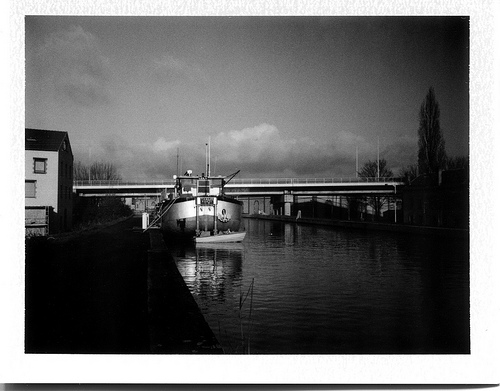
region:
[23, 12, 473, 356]
a black and white photo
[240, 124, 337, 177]
clouds in the sky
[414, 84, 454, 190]
a tree in the distance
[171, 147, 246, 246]
a boat on the water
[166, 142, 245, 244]
a boat parked in the water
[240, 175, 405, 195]
a bridge behind the boat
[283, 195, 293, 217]
column foundation for the bridge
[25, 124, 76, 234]
a house near the water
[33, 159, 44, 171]
a window in the house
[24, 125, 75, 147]
the roof of the house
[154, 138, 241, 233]
a large docked boat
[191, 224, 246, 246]
a small boat in water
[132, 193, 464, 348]
a river of water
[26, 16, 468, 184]
a cloudy hazy sky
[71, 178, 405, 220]
a bridge over water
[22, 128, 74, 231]
a white building in distance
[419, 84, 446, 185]
a tall tree in distance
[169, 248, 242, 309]
reflection of boat in water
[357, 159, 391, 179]
a large tree in distance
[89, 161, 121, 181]
a bare tree in distance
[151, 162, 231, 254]
boat docked on water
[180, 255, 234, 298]
reflection in water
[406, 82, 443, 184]
a tall tree nearby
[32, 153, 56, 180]
small square window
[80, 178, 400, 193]
a large stone bridge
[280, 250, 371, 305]
ripples on the surface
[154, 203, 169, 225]
ropes anchoring the boat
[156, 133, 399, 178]
thick clouds in the sky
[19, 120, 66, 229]
a small warf house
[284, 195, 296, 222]
a stone bridge support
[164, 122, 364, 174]
An ominous low hanging cloud in the sky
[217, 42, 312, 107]
A patch of clear open sky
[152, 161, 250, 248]
A large ship passing beneath a bridge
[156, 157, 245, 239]
A large ship sailing in the water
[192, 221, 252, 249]
A tiny boat in front of the big ship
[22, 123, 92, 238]
A white and black house on the shore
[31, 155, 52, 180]
A small window on the white house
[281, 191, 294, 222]
A concrete pillar of the bridge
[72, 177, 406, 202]
A long bridge behind the large ship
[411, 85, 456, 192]
A tall, healthy tree on land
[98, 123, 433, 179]
cloud low in sky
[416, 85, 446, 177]
tall and thin tree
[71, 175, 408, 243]
bridge spanning over water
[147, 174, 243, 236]
front of docked boat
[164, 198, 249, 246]
smaller boat in front of larger boat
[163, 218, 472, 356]
surface of calm water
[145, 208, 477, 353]
two sides of water canal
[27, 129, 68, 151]
slanted roof of building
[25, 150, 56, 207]
two windows on building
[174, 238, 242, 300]
reflection on water surface